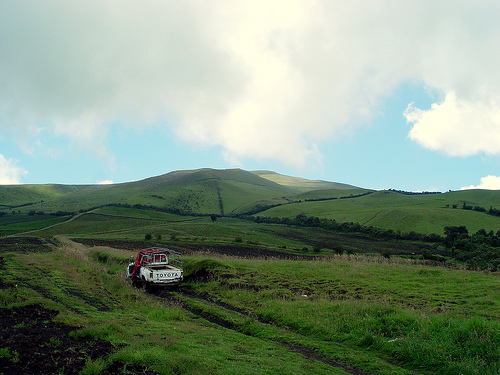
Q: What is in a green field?
A: Mountain range.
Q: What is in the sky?
A: Puffy clouds.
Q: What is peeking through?
A: Blue sky.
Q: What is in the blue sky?
A: Thick white clouds.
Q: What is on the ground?
A: Tire tracks.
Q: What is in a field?
A: An old white Toyota truck.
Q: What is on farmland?
A: An abandoned white truck.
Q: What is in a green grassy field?
A: Two worn paths.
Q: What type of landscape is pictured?
A: A farmland.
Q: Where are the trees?
A: Surrounding the farmland.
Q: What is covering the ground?
A: Grass.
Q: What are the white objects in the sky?
A: Clouds.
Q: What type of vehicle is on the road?
A: A truck.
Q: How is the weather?
A: Cloudy.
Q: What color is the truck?
A: White.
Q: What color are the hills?
A: Green.